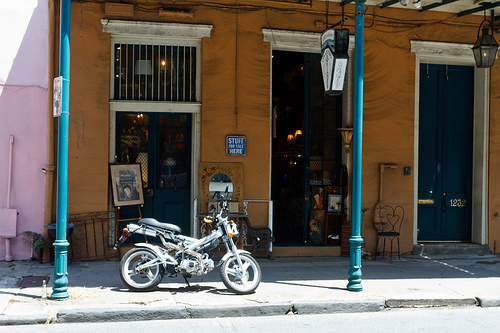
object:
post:
[50, 0, 73, 302]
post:
[348, 5, 365, 294]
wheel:
[119, 246, 166, 295]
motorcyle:
[112, 188, 263, 296]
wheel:
[220, 250, 263, 295]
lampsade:
[133, 60, 157, 76]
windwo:
[103, 19, 210, 241]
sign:
[320, 27, 351, 94]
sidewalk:
[2, 254, 499, 325]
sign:
[227, 135, 248, 153]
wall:
[209, 28, 269, 161]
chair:
[375, 204, 405, 260]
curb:
[4, 296, 499, 322]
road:
[5, 307, 499, 331]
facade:
[0, 1, 50, 260]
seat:
[139, 215, 181, 233]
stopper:
[381, 256, 390, 259]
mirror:
[206, 171, 237, 200]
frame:
[198, 163, 243, 210]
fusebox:
[1, 210, 18, 238]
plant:
[19, 229, 46, 260]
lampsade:
[136, 153, 150, 186]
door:
[417, 65, 474, 240]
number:
[449, 198, 467, 207]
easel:
[109, 163, 145, 239]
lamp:
[471, 16, 497, 68]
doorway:
[270, 48, 351, 251]